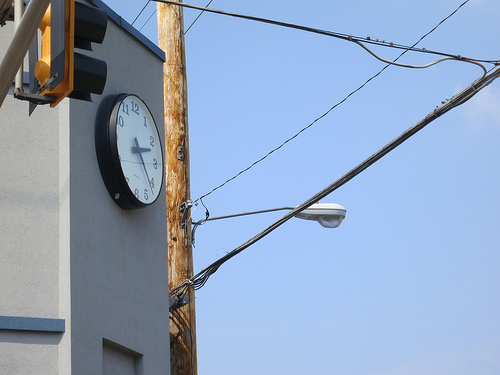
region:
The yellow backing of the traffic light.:
[36, 1, 73, 101]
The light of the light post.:
[299, 200, 348, 229]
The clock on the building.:
[97, 90, 165, 207]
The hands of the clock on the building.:
[131, 129, 158, 182]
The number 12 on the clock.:
[129, 100, 139, 115]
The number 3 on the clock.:
[148, 153, 161, 167]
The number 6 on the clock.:
[133, 179, 142, 197]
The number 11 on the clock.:
[122, 98, 129, 115]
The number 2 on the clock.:
[144, 130, 156, 146]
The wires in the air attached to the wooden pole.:
[162, 1, 498, 329]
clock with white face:
[98, 90, 168, 214]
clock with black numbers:
[100, 88, 165, 214]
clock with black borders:
[96, 92, 169, 216]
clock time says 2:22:
[91, 87, 166, 222]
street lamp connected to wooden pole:
[195, 198, 351, 245]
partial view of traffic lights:
[30, 0, 114, 108]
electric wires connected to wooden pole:
[179, 0, 497, 292]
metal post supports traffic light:
[1, 0, 61, 114]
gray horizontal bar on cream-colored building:
[1, 307, 71, 344]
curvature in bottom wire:
[341, 29, 488, 84]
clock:
[0, 100, 37, 220]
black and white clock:
[99, 90, 162, 213]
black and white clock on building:
[111, 88, 157, 209]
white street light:
[290, 198, 351, 231]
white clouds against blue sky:
[212, 279, 264, 339]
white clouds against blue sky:
[265, 273, 315, 341]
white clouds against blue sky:
[340, 263, 389, 338]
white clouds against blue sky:
[385, 252, 464, 341]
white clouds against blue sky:
[379, 174, 472, 271]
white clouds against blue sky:
[206, 55, 274, 121]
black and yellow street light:
[36, 2, 99, 102]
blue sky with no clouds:
[398, 226, 473, 296]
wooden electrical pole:
[163, 78, 190, 153]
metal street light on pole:
[195, 203, 354, 231]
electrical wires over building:
[254, 14, 482, 71]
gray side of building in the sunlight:
[12, 162, 46, 278]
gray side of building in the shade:
[92, 227, 148, 323]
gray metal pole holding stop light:
[12, 2, 50, 34]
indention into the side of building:
[97, 333, 153, 373]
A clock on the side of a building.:
[94, 79, 169, 224]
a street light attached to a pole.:
[181, 188, 361, 250]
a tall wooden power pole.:
[155, 0, 205, 366]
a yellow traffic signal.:
[0, 0, 124, 120]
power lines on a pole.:
[193, 57, 498, 302]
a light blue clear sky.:
[100, 6, 497, 373]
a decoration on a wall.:
[0, 310, 72, 338]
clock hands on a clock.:
[115, 128, 161, 193]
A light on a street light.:
[316, 205, 355, 245]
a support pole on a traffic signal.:
[0, 5, 54, 111]